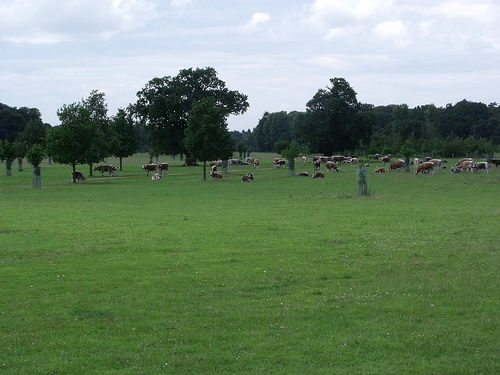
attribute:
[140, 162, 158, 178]
cow — grazing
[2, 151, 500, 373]
field — green, grass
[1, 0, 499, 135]
sky — blue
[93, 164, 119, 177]
cow — brown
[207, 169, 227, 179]
cow — laying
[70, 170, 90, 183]
cow — grazing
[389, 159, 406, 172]
cow — walking, grazing